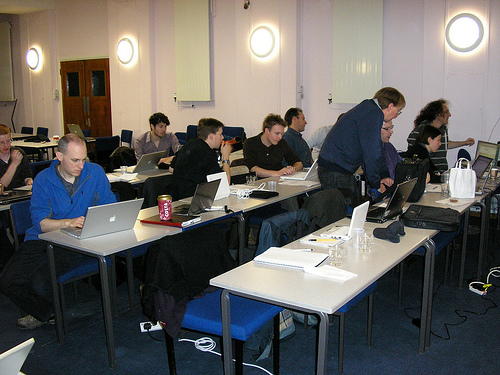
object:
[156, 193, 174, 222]
can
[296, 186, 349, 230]
jacket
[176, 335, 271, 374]
cord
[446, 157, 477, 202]
bag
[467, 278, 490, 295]
cables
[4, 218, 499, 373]
floor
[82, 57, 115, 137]
doors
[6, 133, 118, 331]
man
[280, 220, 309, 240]
collar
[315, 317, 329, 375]
leg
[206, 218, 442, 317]
top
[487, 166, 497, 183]
cup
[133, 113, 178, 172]
man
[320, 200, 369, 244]
laptop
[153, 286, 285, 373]
seat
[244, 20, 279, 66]
light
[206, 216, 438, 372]
desk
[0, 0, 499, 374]
room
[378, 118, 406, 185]
person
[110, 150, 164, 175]
computer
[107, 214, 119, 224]
logo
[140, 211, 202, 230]
book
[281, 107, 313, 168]
student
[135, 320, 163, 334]
powerstrip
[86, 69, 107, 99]
windows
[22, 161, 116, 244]
sweater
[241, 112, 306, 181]
kids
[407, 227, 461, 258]
chair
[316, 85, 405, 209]
man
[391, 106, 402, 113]
glasses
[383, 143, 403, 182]
sweathirt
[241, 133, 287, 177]
shirt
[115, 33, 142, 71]
light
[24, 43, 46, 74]
light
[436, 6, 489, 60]
light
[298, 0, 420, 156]
wall